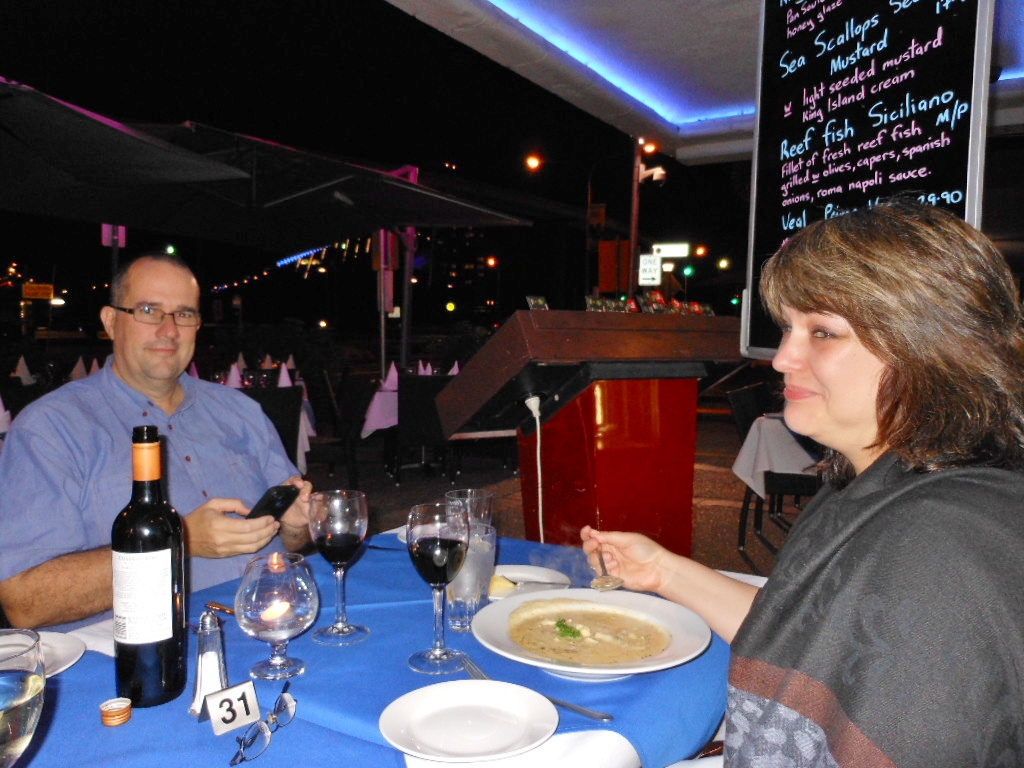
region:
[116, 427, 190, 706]
The dark wine bottle.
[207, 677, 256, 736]
The table reservation number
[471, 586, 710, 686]
A white plate with soup.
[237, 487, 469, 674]
Glasses of wine on a table.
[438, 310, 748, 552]
The wooden address pulpit.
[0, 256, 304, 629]
The man wearing a blue shirt.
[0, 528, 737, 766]
A dining table with a blue table cloth.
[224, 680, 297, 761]
The eye glasses on the table.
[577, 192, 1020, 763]
Woman holding a spoon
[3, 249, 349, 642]
Man looking up from a cell phone that is in his hands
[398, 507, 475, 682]
Glass of red wine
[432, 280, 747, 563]
Podium with a red base and brown top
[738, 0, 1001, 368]
Chalk board with writing on it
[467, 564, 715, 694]
Bowl of soup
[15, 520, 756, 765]
Table with blue table cloth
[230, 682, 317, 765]
Pair of folded up eye glasses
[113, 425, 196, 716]
Opened bottle of wine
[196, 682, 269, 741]
Small placard with the number 31 written on it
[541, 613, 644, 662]
food on the plate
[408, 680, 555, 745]
plate on the table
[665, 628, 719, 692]
plate on the table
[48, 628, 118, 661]
plate on the table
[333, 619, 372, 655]
glass on the table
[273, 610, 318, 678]
glass on the table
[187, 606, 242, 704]
glass on the table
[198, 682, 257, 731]
white sign with table number on blue table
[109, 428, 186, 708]
brown bottle of wine with orange and white labels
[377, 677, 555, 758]
empty round white plate on table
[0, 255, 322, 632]
man in blue shirt with glasses holds black cell phone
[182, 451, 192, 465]
small brown button on blue shirt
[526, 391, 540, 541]
white cord plugged into wooden podium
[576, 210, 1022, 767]
woman with brown hair eats creamy soup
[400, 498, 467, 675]
glass of wine on blue table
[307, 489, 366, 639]
glass of wine on blue table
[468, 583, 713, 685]
large round white bowl of creamy soup with green garnish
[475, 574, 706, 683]
the white bowl is filled with soup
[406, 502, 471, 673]
a glass with red wine in it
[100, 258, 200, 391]
the man is wearing eyeglasses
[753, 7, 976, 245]
a menu written on a black board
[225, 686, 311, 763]
the eyeglasses are laying on the blue tablecloth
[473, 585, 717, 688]
A bowl of soup with a green vegetable on top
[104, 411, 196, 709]
A bottle of wine on a table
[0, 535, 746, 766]
A blue table full of food and glasses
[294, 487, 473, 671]
Two glasses of wine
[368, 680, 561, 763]
An empty white plate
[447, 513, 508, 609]
A glass of water on a blue table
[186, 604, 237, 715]
A clear salt shaker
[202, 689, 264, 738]
The number thirty-one on a white card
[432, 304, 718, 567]
A podium in a restaurant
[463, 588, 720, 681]
Bowl of soup on the table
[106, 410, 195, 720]
Open bottle of wine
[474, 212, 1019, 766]
Woman eating a bowl of soup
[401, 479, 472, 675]
Glass of red wine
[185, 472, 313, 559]
Cell phone in man's hand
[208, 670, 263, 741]
The number 31 on a sign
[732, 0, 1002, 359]
Menu board hanging behind the woman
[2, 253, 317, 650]
Man seated at the table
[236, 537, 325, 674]
Candle in a glass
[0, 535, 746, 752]
Blue tablecloth on the table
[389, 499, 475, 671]
a tall wine glass